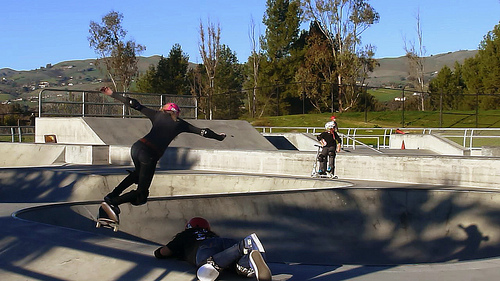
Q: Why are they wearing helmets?
A: Protect head.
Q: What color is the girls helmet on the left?
A: Pink.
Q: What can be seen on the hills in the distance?
A: Houses.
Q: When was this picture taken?
A: Day time.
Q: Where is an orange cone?
A: Right side in background.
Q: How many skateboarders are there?
A: Three.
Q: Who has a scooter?
A: Little girl white helmet.